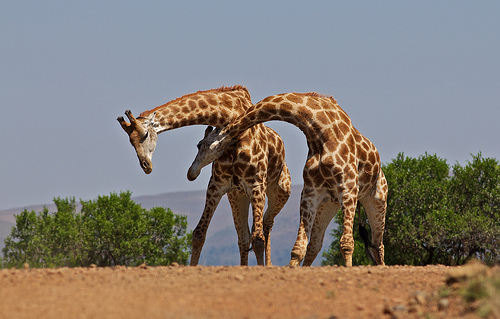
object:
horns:
[123, 108, 139, 128]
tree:
[320, 150, 472, 267]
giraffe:
[117, 86, 289, 265]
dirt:
[0, 261, 498, 318]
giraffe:
[187, 92, 390, 268]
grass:
[439, 270, 499, 317]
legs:
[188, 187, 226, 266]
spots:
[337, 141, 352, 165]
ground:
[0, 259, 500, 318]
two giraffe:
[118, 84, 390, 265]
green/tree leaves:
[30, 213, 40, 223]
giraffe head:
[117, 108, 159, 176]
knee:
[248, 227, 268, 247]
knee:
[340, 232, 359, 256]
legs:
[338, 178, 359, 268]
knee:
[190, 228, 207, 246]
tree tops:
[4, 190, 192, 239]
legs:
[360, 201, 389, 266]